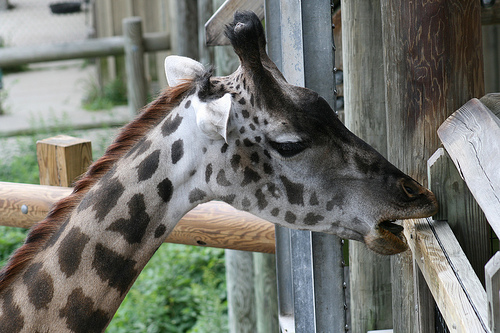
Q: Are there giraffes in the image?
A: Yes, there is a giraffe.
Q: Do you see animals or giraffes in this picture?
A: Yes, there is a giraffe.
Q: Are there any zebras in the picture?
A: No, there are no zebras.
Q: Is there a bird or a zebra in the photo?
A: No, there are no zebras or birds.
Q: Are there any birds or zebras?
A: No, there are no zebras or birds.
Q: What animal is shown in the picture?
A: The animal is a giraffe.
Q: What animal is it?
A: The animal is a giraffe.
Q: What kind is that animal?
A: This is a giraffe.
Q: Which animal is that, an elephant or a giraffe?
A: This is a giraffe.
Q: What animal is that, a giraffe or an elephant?
A: This is a giraffe.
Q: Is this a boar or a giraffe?
A: This is a giraffe.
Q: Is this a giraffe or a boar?
A: This is a giraffe.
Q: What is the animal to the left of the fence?
A: The animal is a giraffe.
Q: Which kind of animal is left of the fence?
A: The animal is a giraffe.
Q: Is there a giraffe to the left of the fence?
A: Yes, there is a giraffe to the left of the fence.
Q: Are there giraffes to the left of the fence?
A: Yes, there is a giraffe to the left of the fence.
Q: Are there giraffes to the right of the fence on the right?
A: No, the giraffe is to the left of the fence.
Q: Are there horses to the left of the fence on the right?
A: No, there is a giraffe to the left of the fence.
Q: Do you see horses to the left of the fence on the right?
A: No, there is a giraffe to the left of the fence.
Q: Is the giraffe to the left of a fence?
A: Yes, the giraffe is to the left of a fence.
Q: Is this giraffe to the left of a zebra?
A: No, the giraffe is to the left of a fence.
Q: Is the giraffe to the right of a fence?
A: No, the giraffe is to the left of a fence.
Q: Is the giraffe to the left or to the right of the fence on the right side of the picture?
A: The giraffe is to the left of the fence.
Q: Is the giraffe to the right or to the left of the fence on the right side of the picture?
A: The giraffe is to the left of the fence.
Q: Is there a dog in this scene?
A: No, there are no dogs.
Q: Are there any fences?
A: Yes, there is a fence.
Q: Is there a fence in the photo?
A: Yes, there is a fence.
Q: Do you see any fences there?
A: Yes, there is a fence.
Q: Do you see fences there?
A: Yes, there is a fence.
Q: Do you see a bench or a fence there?
A: Yes, there is a fence.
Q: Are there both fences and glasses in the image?
A: No, there is a fence but no glasses.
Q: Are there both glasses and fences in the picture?
A: No, there is a fence but no glasses.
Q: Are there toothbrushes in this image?
A: No, there are no toothbrushes.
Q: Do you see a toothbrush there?
A: No, there are no toothbrushes.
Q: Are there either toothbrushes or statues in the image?
A: No, there are no toothbrushes or statues.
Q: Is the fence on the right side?
A: Yes, the fence is on the right of the image.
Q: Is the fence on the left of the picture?
A: No, the fence is on the right of the image.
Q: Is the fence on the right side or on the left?
A: The fence is on the right of the image.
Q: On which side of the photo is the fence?
A: The fence is on the right of the image.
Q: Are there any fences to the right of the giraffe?
A: Yes, there is a fence to the right of the giraffe.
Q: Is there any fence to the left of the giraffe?
A: No, the fence is to the right of the giraffe.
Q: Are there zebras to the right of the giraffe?
A: No, there is a fence to the right of the giraffe.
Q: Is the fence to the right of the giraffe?
A: Yes, the fence is to the right of the giraffe.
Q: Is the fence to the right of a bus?
A: No, the fence is to the right of the giraffe.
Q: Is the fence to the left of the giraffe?
A: No, the fence is to the right of the giraffe.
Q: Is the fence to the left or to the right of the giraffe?
A: The fence is to the right of the giraffe.